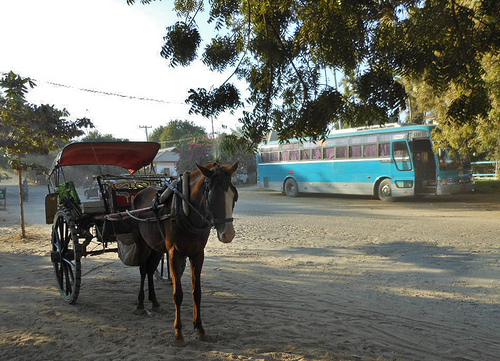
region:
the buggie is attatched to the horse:
[46, 132, 279, 349]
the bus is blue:
[249, 115, 497, 213]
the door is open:
[392, 136, 443, 200]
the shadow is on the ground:
[344, 228, 494, 290]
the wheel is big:
[42, 205, 89, 305]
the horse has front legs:
[161, 260, 215, 347]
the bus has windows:
[262, 145, 391, 161]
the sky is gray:
[93, 63, 151, 89]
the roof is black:
[163, 151, 175, 162]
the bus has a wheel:
[280, 176, 299, 199]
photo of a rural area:
[0, 5, 499, 357]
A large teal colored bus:
[255, 130, 452, 200]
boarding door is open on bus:
[405, 135, 436, 191]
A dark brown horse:
[164, 160, 239, 338]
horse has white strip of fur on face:
[219, 185, 235, 243]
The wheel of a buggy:
[49, 209, 82, 299]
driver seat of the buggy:
[95, 171, 156, 198]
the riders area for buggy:
[65, 166, 138, 199]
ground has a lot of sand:
[213, 255, 438, 357]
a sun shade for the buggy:
[59, 137, 161, 170]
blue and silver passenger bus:
[255, 120, 467, 194]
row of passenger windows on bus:
[250, 135, 406, 166]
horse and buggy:
[27, 120, 262, 325]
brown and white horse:
[120, 143, 255, 353]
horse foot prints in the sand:
[108, 318, 304, 358]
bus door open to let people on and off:
[395, 125, 442, 200]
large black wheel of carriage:
[49, 207, 82, 295]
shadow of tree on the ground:
[12, 220, 484, 355]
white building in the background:
[141, 138, 201, 182]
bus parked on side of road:
[248, 117, 470, 198]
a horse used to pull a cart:
[126, 160, 248, 350]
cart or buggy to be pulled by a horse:
[37, 136, 177, 300]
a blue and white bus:
[253, 118, 481, 203]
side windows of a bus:
[253, 140, 397, 161]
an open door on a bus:
[389, 134, 441, 196]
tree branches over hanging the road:
[153, 3, 491, 115]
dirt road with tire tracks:
[271, 202, 498, 354]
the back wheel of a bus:
[281, 175, 302, 200]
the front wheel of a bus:
[375, 175, 395, 202]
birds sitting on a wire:
[32, 71, 182, 113]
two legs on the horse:
[130, 244, 160, 310]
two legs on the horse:
[164, 243, 221, 343]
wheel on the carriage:
[41, 205, 97, 306]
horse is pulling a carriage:
[40, 128, 255, 343]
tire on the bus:
[280, 173, 304, 200]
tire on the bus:
[372, 172, 397, 212]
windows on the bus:
[256, 140, 400, 164]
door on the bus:
[386, 138, 436, 205]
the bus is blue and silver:
[247, 120, 487, 202]